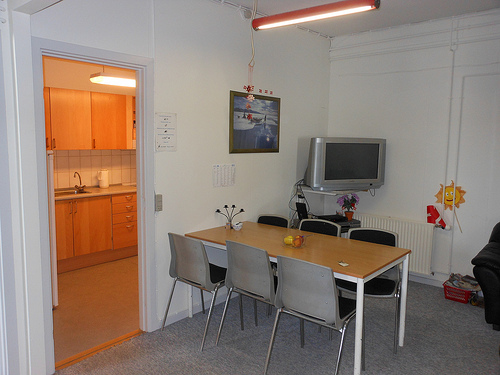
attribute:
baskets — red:
[442, 276, 474, 300]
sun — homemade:
[430, 183, 470, 212]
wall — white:
[333, 26, 484, 273]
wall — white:
[153, 10, 365, 327]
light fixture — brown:
[248, 6, 388, 32]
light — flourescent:
[260, 9, 378, 29]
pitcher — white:
[94, 167, 108, 188]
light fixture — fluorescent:
[92, 74, 137, 92]